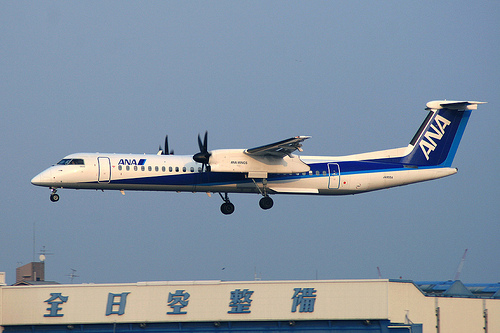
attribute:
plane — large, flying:
[91, 92, 491, 248]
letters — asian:
[70, 275, 346, 330]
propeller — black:
[181, 136, 226, 180]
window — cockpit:
[65, 150, 97, 169]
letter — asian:
[15, 287, 86, 329]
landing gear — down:
[192, 183, 295, 213]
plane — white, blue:
[80, 110, 463, 246]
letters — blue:
[39, 257, 377, 325]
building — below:
[31, 251, 450, 329]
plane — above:
[43, 99, 491, 245]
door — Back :
[322, 159, 482, 183]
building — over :
[3, 243, 484, 328]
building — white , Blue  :
[4, 263, 480, 331]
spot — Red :
[339, 177, 352, 187]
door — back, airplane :
[322, 160, 343, 189]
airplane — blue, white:
[31, 93, 481, 231]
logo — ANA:
[414, 114, 452, 159]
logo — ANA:
[116, 154, 149, 173]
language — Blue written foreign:
[37, 280, 325, 324]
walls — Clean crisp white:
[219, 156, 314, 179]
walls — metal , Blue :
[333, 154, 399, 174]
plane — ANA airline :
[28, 99, 476, 222]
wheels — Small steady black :
[221, 199, 271, 217]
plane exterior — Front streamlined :
[27, 97, 482, 213]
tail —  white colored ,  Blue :
[400, 89, 481, 171]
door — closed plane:
[97, 154, 114, 177]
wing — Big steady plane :
[247, 123, 314, 172]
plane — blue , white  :
[28, 96, 482, 211]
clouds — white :
[296, 75, 338, 106]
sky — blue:
[8, 8, 467, 128]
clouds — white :
[271, 51, 364, 96]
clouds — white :
[259, 27, 342, 107]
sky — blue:
[6, 6, 483, 99]